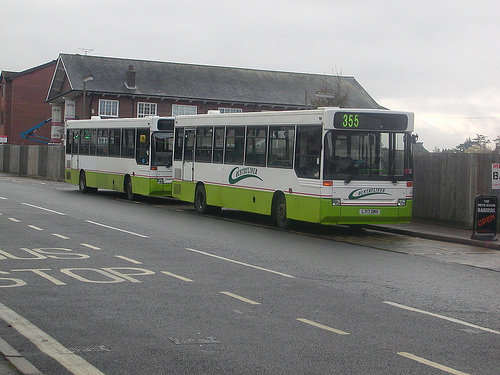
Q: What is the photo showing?
A: It is showing a street.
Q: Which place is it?
A: It is a street.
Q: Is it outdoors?
A: Yes, it is outdoors.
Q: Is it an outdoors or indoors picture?
A: It is outdoors.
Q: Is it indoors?
A: No, it is outdoors.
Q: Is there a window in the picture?
A: Yes, there is a window.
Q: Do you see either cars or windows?
A: Yes, there is a window.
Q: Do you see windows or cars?
A: Yes, there is a window.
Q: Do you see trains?
A: No, there are no trains.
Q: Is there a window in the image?
A: Yes, there is a window.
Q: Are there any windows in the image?
A: Yes, there is a window.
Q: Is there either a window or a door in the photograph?
A: Yes, there is a window.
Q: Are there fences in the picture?
A: Yes, there is a fence.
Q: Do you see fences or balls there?
A: Yes, there is a fence.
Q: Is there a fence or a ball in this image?
A: Yes, there is a fence.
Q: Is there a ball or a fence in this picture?
A: Yes, there is a fence.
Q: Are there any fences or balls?
A: Yes, there is a fence.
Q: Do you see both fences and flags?
A: No, there is a fence but no flags.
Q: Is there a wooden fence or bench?
A: Yes, there is a wood fence.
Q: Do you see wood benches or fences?
A: Yes, there is a wood fence.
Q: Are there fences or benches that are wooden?
A: Yes, the fence is wooden.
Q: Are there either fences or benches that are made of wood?
A: Yes, the fence is made of wood.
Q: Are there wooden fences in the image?
A: Yes, there is a wood fence.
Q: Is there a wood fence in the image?
A: Yes, there is a wood fence.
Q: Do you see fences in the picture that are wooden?
A: Yes, there is a fence that is wooden.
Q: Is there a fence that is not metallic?
A: Yes, there is a wooden fence.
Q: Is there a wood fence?
A: Yes, there is a fence that is made of wood.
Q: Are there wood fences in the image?
A: Yes, there is a fence that is made of wood.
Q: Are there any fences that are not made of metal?
A: Yes, there is a fence that is made of wood.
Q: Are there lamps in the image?
A: No, there are no lamps.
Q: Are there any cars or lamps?
A: No, there are no lamps or cars.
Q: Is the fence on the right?
A: Yes, the fence is on the right of the image.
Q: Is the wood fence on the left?
A: No, the fence is on the right of the image.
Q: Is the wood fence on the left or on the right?
A: The fence is on the right of the image.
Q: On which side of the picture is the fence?
A: The fence is on the right of the image.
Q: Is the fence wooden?
A: Yes, the fence is wooden.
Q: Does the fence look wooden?
A: Yes, the fence is wooden.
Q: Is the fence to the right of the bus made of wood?
A: Yes, the fence is made of wood.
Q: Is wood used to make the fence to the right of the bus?
A: Yes, the fence is made of wood.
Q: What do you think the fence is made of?
A: The fence is made of wood.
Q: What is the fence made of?
A: The fence is made of wood.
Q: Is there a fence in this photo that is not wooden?
A: No, there is a fence but it is wooden.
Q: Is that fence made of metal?
A: No, the fence is made of wood.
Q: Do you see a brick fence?
A: No, there is a fence but it is made of wood.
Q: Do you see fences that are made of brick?
A: No, there is a fence but it is made of wood.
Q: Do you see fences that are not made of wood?
A: No, there is a fence but it is made of wood.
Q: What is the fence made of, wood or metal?
A: The fence is made of wood.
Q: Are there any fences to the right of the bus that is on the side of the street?
A: Yes, there is a fence to the right of the bus.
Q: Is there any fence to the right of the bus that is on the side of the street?
A: Yes, there is a fence to the right of the bus.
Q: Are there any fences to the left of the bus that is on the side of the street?
A: No, the fence is to the right of the bus.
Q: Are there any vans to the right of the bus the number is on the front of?
A: No, there is a fence to the right of the bus.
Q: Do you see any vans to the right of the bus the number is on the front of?
A: No, there is a fence to the right of the bus.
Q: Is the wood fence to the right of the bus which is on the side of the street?
A: Yes, the fence is to the right of the bus.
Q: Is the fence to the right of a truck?
A: No, the fence is to the right of the bus.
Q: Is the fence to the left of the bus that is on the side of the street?
A: No, the fence is to the right of the bus.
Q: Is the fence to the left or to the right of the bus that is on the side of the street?
A: The fence is to the right of the bus.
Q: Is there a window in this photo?
A: Yes, there is a window.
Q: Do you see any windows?
A: Yes, there is a window.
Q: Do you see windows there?
A: Yes, there is a window.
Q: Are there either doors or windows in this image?
A: Yes, there is a window.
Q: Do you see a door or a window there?
A: Yes, there is a window.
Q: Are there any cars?
A: No, there are no cars.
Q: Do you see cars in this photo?
A: No, there are no cars.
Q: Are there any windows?
A: Yes, there is a window.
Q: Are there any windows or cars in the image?
A: Yes, there is a window.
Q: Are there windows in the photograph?
A: Yes, there is a window.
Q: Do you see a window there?
A: Yes, there is a window.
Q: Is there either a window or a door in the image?
A: Yes, there is a window.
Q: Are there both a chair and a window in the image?
A: No, there is a window but no chairs.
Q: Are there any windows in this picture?
A: Yes, there is a window.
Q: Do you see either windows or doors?
A: Yes, there is a window.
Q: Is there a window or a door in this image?
A: Yes, there is a window.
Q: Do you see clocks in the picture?
A: No, there are no clocks.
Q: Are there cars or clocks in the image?
A: No, there are no clocks or cars.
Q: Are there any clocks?
A: No, there are no clocks.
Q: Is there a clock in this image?
A: No, there are no clocks.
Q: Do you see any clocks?
A: No, there are no clocks.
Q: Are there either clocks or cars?
A: No, there are no clocks or cars.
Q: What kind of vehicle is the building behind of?
A: The building is behind the bus.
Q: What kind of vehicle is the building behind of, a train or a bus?
A: The building is behind a bus.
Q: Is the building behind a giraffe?
A: No, the building is behind the bus.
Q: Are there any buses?
A: Yes, there is a bus.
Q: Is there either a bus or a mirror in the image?
A: Yes, there is a bus.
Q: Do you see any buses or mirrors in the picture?
A: Yes, there is a bus.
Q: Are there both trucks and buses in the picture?
A: No, there is a bus but no trucks.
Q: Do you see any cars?
A: No, there are no cars.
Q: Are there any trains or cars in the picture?
A: No, there are no cars or trains.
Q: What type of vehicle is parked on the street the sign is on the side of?
A: The vehicle is a bus.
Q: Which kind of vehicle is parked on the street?
A: The vehicle is a bus.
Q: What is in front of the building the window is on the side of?
A: The bus is in front of the building.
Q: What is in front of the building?
A: The bus is in front of the building.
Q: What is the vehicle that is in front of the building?
A: The vehicle is a bus.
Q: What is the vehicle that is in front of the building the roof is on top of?
A: The vehicle is a bus.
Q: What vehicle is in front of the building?
A: The vehicle is a bus.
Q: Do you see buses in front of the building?
A: Yes, there is a bus in front of the building.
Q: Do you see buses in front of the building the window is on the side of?
A: Yes, there is a bus in front of the building.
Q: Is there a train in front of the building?
A: No, there is a bus in front of the building.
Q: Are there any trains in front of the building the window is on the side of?
A: No, there is a bus in front of the building.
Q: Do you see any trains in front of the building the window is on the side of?
A: No, there is a bus in front of the building.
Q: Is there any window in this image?
A: Yes, there is a window.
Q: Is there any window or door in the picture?
A: Yes, there is a window.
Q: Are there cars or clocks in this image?
A: No, there are no cars or clocks.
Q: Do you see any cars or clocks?
A: No, there are no cars or clocks.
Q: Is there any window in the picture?
A: Yes, there is a window.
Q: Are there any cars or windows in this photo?
A: Yes, there is a window.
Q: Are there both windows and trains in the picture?
A: No, there is a window but no trains.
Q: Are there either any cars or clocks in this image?
A: No, there are no clocks or cars.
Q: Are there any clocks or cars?
A: No, there are no clocks or cars.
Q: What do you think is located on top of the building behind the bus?
A: The roof is on top of the building.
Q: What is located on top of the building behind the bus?
A: The roof is on top of the building.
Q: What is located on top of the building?
A: The roof is on top of the building.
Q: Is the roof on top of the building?
A: Yes, the roof is on top of the building.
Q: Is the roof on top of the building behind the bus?
A: Yes, the roof is on top of the building.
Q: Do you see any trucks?
A: No, there are no trucks.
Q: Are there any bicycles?
A: No, there are no bicycles.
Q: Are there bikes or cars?
A: No, there are no bikes or cars.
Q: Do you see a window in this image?
A: Yes, there is a window.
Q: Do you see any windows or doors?
A: Yes, there is a window.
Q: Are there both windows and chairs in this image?
A: No, there is a window but no chairs.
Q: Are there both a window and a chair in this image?
A: No, there is a window but no chairs.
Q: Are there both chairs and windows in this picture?
A: No, there is a window but no chairs.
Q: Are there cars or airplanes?
A: No, there are no cars or airplanes.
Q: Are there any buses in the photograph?
A: Yes, there is a bus.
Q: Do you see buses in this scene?
A: Yes, there is a bus.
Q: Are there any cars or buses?
A: Yes, there is a bus.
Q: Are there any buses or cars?
A: Yes, there is a bus.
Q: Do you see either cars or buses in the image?
A: Yes, there is a bus.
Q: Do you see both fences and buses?
A: Yes, there are both a bus and a fence.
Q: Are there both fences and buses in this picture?
A: Yes, there are both a bus and a fence.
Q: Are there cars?
A: No, there are no cars.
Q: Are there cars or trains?
A: No, there are no cars or trains.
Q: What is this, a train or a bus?
A: This is a bus.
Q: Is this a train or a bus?
A: This is a bus.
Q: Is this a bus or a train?
A: This is a bus.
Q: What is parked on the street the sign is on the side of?
A: The bus is parked on the street.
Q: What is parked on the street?
A: The bus is parked on the street.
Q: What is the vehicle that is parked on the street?
A: The vehicle is a bus.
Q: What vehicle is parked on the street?
A: The vehicle is a bus.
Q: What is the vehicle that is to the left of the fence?
A: The vehicle is a bus.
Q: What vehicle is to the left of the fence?
A: The vehicle is a bus.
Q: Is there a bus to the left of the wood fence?
A: Yes, there is a bus to the left of the fence.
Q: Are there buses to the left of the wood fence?
A: Yes, there is a bus to the left of the fence.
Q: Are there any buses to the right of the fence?
A: No, the bus is to the left of the fence.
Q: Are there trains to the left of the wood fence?
A: No, there is a bus to the left of the fence.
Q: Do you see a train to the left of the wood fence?
A: No, there is a bus to the left of the fence.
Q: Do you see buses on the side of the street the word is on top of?
A: Yes, there is a bus on the side of the street.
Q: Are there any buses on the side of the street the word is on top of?
A: Yes, there is a bus on the side of the street.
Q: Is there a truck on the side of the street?
A: No, there is a bus on the side of the street.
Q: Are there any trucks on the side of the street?
A: No, there is a bus on the side of the street.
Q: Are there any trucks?
A: No, there are no trucks.